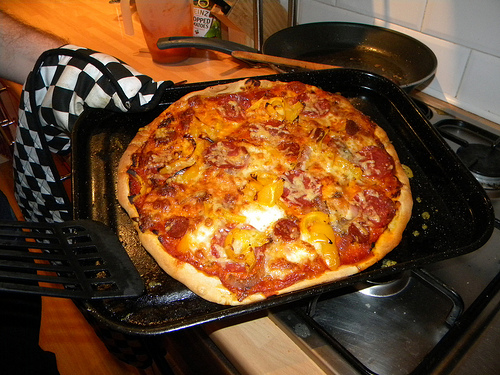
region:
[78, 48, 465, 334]
the pizza has tomato sauce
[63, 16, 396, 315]
the peppers are yellow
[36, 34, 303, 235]
this oven mitt is checked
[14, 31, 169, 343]
the hand has a mitt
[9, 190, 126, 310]
the spatula is steel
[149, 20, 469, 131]
the pan is cast iron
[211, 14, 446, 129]
the tool is wooden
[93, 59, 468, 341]
the pizza is on the pan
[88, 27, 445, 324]
the pizza has been freshly baked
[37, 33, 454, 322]
the cheese is melted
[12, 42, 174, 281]
A black and white potholder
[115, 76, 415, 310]
A pizza with chese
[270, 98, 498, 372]
A gas-operated oven top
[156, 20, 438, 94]
A frying pan in the background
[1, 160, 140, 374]
A light brown floor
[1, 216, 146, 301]
A black spatura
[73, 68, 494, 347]
A black baking pan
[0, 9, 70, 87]
A hand wearing a potholder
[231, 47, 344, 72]
A piece of cookware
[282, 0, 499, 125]
Tiled wall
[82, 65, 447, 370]
a cooked pizza on a pan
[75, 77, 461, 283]
a cooked pizza with peporoni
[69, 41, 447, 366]
a baked pizza on a pan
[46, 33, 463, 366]
someone holding a pan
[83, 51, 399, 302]
someone holding a pan with pizza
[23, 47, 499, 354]
a large spatula on the pan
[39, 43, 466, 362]
an uncut bake pizza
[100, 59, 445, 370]
a baked pizza with red sauce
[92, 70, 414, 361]
baked pizza with cheese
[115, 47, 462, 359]
a pizza with banana pepper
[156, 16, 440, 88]
Black frying pan with black handle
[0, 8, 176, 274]
Hand wearing a black and white oven mit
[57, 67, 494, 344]
Pizza on a black, rectangular tray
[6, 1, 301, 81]
Two bottles and knife block on wooden counter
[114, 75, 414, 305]
Round pizza with tomatoes, cheese and peppers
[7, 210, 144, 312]
End of black plastic spatula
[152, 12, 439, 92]
Dirty black pan with wooden utensil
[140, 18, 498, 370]
Pan sitting on black, silver and wood stove top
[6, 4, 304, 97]
Pale wood kitchen counter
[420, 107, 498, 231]
Black burner on silver stove top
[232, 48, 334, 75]
the wooden handle in the pot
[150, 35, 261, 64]
the metal handle of the pan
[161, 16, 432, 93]
a black metal pan on the stove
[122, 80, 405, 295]
a handmade cooked pizza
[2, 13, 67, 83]
the arm of a person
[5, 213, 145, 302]
the end of a black spatula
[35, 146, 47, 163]
the black square on a hotmitt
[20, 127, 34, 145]
the black square on a hotmitt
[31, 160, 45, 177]
the black square on a hotmitt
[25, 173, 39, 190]
the black square on a hotmitt